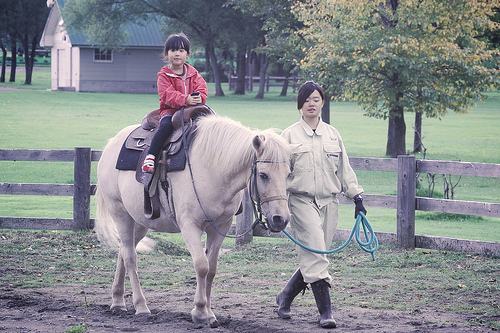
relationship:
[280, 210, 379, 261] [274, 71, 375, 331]
blue rope held by woman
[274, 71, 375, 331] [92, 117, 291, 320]
woman leading horse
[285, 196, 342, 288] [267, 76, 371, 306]
khaki pants worn by woman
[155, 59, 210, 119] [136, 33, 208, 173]
jacket worn by asian girl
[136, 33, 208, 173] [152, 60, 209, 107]
asian girl wearing jacket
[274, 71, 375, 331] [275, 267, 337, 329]
woman wearing boots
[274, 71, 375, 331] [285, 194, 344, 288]
woman wearing khaki pants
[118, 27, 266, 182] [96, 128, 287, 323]
asian girl riding horse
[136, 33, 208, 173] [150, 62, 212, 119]
asian girl wearing jacket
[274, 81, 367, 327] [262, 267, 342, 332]
woman in boots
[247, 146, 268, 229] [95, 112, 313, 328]
bridle on horse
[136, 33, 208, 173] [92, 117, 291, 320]
asian girl riding horse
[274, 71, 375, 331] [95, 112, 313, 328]
woman leading horse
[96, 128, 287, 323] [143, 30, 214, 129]
horse ridden by girl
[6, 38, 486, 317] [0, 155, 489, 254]
land enclosed by fence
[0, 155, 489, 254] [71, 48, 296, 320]
fence for horse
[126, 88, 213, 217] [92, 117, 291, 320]
saddle on horse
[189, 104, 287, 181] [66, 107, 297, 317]
hair on horse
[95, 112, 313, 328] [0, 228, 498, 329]
horse walking in dirt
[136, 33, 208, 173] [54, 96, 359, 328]
asian girl riding on horse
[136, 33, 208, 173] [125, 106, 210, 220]
asian girl sitting on saddle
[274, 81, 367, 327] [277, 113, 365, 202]
woman wearing shirt